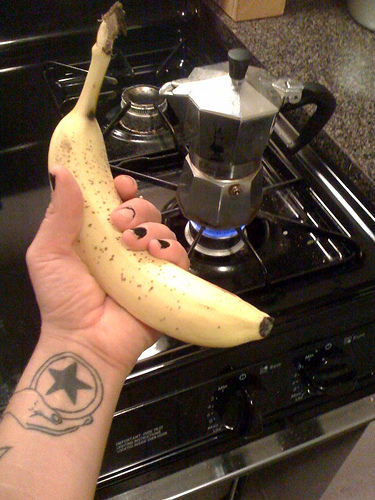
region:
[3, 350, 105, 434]
a persons arm with a tattoo on it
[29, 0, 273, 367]
a person hand holding a banana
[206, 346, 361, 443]
control knobs on a round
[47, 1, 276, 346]
a yellow banana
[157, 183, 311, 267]
blue gas flames coming out of a burner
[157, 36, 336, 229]
a silver and black tea pot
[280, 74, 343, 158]
black handle on a tea pot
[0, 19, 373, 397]
a black stove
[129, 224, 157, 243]
black finger nail polish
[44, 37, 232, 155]
a round on a stove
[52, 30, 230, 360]
A evenly ripe banana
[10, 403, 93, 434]
A hand tatoo on a hand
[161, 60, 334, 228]
A Kattle on a cooker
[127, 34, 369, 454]
A lit electric cooker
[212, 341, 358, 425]
Black knobs of an electric cooker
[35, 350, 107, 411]
Star tatoo on a hand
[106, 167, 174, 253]
Poorly polished finger nails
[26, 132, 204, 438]
An arm holding a banana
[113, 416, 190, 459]
Disclaimer on the cooker on usage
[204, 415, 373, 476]
oven below the cooker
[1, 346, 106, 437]
Tattoo on wrist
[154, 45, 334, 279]
Coffee pot on stove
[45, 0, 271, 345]
Hand holding a banana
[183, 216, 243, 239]
blue flame from burner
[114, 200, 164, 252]
chipped black nail polish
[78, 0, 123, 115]
Stem of a banana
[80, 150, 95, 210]
Brown spots on a banana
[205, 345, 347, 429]
Two stove top control knobs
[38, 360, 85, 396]
Star tattoo on wrist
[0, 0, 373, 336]
Black stove top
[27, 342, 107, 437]
Tattoo on a wrist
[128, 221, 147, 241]
Black fingernail polish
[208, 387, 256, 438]
Control knob for the cooktop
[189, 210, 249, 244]
Blue flame on the gas stove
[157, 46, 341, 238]
Odd looking coffeepot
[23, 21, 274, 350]
Ripe yellow banana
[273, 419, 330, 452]
Reflection of a control knob in the chrome trim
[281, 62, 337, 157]
Handle of a coffee pot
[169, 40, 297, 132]
Hinged lid on a coffee pot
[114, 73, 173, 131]
Unused burner on a stove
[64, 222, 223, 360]
The banana is a person hand.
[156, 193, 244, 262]
The stove burner is on.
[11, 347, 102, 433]
The person have a tattoo star on wrist.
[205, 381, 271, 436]
The black knobs on the stove.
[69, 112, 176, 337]
The banana is yellow.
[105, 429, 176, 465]
The stove has white writing.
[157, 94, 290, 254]
A teapot on top of the stove.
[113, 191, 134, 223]
Nail polish is missing off one of the fingers.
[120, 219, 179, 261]
The fingers have black nail polish.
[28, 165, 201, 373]
A person is standing by the stove